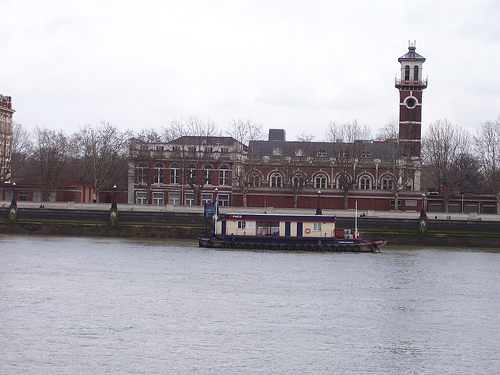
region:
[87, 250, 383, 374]
the water is calm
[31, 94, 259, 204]
the trees have no leaves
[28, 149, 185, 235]
trees are made of wood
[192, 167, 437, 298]
little building next to water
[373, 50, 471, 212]
tower on building by the water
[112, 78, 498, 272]
the building is red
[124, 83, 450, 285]
the building is made of bricks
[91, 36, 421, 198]
the sky is cloudy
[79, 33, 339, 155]
the clouds are white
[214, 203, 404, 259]
the building is light yellow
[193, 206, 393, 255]
a boat on the river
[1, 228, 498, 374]
a placid river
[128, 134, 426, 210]
a red brick biulding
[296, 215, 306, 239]
a door on a boat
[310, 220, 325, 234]
a window on a boat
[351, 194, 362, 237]
a white pole on a boat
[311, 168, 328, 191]
an arched window on a building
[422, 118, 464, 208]
a bare leafless tree near the river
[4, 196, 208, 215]
a railing on the river's edge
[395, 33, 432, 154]
a tower on the roof of a building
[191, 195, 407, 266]
the boat on the water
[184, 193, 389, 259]
the boat is blue and cream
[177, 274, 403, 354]
the water is calm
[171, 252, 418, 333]
the water is moving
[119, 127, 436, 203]
the building beside the water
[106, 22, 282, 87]
the sky is gray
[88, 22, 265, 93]
the sky is cloudy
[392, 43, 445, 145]
the tower on the building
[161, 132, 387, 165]
the roof of the building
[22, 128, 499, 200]
the trees without leaves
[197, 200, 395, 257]
A riverboat on the water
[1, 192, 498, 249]
A silver and blue train by the river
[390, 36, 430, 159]
A clock tower attached to the building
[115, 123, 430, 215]
A red two-story building with rounded windows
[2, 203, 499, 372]
A lightly rippling river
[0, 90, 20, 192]
A tall red and white building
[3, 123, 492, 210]
A line of leafless trees by the river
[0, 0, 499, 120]
Grey, cloudy sky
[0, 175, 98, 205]
A low orange building with white windows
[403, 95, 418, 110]
a clock on the tower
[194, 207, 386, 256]
a boat on the water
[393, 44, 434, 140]
a tower on a building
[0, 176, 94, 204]
a low brick building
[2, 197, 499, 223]
a road alongside a river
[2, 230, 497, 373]
a smooth, placid river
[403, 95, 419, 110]
a circular window on a tour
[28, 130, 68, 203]
a bare leafless tree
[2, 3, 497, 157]
a bright gray sky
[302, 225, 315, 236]
a round orange life preserver on a boat